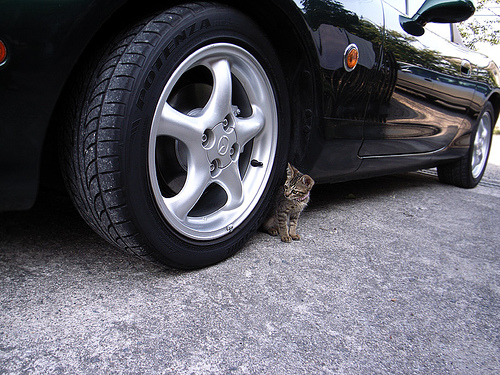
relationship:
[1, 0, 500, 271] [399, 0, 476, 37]
car has mirror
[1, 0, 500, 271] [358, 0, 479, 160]
car has door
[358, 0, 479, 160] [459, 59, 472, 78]
door has handle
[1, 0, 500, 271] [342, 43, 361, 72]
car has reflector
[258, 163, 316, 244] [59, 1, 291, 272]
kitten hiding behind wheel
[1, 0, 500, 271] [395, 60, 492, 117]
car reflects car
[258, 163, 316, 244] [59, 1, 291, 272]
kitten near wheel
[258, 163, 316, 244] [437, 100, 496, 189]
kitten near tire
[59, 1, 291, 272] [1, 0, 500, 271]
wheel mounted on car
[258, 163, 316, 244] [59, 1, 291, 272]
kitten standing to right of wheel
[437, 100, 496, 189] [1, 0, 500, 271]
tire mounted on car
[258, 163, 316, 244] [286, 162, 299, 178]
kitten has ear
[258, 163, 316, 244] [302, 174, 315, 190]
kitten has ear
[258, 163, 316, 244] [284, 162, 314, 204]
kitten has head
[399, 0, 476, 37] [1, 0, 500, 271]
mirror mounted on car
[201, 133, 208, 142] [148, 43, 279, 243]
lug nut attached to wheel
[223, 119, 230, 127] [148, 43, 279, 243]
lug nut attached to wheel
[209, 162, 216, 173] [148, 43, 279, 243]
lug nut attached to wheel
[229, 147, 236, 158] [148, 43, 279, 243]
lug nut attached to wheel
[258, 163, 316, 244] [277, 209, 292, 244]
kitten has leg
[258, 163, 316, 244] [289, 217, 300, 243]
kitten has leg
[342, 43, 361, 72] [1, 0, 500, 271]
reflector on drivers side of car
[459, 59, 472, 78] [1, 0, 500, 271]
handle on drivers side of car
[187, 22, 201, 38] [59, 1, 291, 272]
z printed on wheel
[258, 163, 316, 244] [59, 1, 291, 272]
kitten beside wheel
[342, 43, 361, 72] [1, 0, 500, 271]
reflector on side of car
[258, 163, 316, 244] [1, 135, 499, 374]
kitten sitting on ground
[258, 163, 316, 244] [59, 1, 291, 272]
kitten next to wheel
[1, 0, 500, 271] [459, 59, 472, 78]
car has handle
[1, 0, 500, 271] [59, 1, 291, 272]
car has wheel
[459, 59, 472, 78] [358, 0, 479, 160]
handle attached to door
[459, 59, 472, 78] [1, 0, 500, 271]
handle attached to car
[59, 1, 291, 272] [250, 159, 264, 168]
wheel has air valve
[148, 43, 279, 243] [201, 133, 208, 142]
wheel has lug nut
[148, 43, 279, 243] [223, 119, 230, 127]
wheel has lug nut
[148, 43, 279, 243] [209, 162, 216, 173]
wheel has lug nut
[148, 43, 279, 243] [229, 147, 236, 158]
wheel has lug nut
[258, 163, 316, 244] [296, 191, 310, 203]
kitten wearing collar